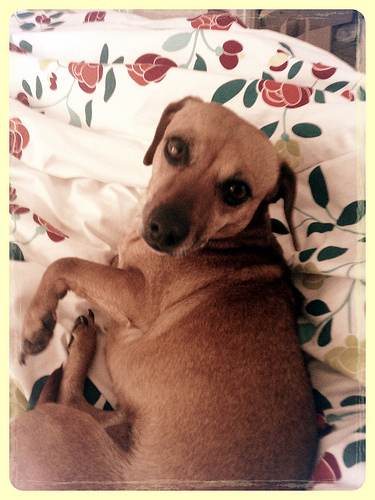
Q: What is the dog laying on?
A: Blanket.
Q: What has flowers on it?
A: Blanket.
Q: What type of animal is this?
A: Dog.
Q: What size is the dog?
A: Small.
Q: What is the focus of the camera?
A: Dog's eyes.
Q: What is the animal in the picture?
A: Dog.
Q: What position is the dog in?
A: Laying down.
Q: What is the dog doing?
A: Laying down.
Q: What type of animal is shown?
A: Dog.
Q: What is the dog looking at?
A: Camera.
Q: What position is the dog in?
A: Laying.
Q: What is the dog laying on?
A: Bedspread.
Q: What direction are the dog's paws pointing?
A: Left.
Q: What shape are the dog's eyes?
A: Round.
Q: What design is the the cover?
A: Floral.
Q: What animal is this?
A: A dog.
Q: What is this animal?
A: Dog.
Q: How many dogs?
A: One.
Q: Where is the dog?
A: On a bed.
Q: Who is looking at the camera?
A: A dog.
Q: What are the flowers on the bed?
A: Roses.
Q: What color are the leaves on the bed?
A: Green.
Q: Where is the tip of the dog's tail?
A: Lower left quadrant.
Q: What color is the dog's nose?
A: Black.